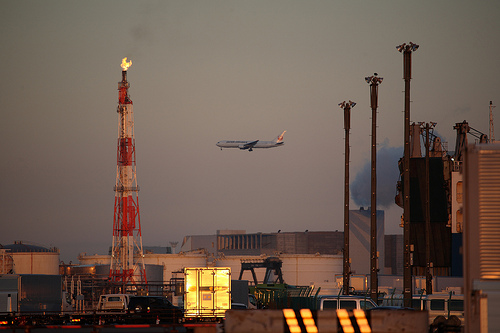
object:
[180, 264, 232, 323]
truck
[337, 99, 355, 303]
mast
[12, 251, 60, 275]
silo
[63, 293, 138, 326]
truck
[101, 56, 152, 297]
tower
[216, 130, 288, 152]
plane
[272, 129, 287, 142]
tail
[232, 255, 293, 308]
machine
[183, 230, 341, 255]
building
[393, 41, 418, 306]
mast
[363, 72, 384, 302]
mast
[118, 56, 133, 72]
flame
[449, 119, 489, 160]
machinery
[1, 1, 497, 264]
sky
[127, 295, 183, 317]
car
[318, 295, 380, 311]
car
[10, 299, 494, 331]
ground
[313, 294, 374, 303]
roof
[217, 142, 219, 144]
window